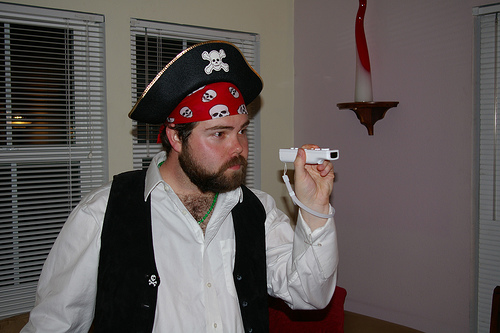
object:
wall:
[290, 0, 478, 332]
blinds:
[0, 3, 109, 331]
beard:
[175, 140, 250, 197]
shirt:
[19, 151, 341, 331]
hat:
[124, 41, 264, 127]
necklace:
[197, 192, 222, 232]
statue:
[352, 0, 372, 103]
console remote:
[277, 147, 340, 167]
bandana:
[154, 82, 250, 145]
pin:
[137, 271, 162, 313]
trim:
[126, 38, 264, 126]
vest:
[90, 167, 267, 332]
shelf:
[334, 101, 402, 137]